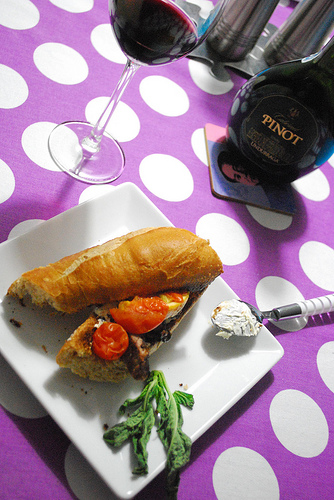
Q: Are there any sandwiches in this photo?
A: Yes, there is a sandwich.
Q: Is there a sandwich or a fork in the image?
A: Yes, there is a sandwich.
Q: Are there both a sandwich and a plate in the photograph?
A: Yes, there are both a sandwich and a plate.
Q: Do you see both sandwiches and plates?
A: Yes, there are both a sandwich and a plate.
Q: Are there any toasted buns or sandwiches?
A: Yes, there is a toasted sandwich.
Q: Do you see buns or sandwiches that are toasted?
A: Yes, the sandwich is toasted.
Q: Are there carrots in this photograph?
A: No, there are no carrots.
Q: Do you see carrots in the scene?
A: No, there are no carrots.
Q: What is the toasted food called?
A: The food is a sandwich.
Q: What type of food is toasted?
A: The food is a sandwich.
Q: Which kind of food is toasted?
A: The food is a sandwich.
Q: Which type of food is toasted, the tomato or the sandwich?
A: The sandwich is toasted.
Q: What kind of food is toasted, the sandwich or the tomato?
A: The sandwich is toasted.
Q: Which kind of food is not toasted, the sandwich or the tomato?
A: The tomato is not toasted.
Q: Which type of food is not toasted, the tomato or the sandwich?
A: The tomato is not toasted.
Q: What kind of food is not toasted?
A: The food is a tomato.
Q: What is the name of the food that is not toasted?
A: The food is a tomato.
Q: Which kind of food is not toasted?
A: The food is a tomato.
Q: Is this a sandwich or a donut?
A: This is a sandwich.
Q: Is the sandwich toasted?
A: Yes, the sandwich is toasted.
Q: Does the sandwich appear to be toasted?
A: Yes, the sandwich is toasted.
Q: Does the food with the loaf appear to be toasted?
A: Yes, the sandwich is toasted.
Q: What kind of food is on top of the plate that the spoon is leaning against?
A: The food is a sandwich.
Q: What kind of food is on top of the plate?
A: The food is a sandwich.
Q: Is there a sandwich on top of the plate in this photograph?
A: Yes, there is a sandwich on top of the plate.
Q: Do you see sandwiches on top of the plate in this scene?
A: Yes, there is a sandwich on top of the plate.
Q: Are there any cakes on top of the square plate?
A: No, there is a sandwich on top of the plate.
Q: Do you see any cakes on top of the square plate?
A: No, there is a sandwich on top of the plate.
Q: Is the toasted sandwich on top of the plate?
A: Yes, the sandwich is on top of the plate.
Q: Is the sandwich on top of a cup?
A: No, the sandwich is on top of the plate.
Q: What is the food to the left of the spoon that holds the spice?
A: The food is a sandwich.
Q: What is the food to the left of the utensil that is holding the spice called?
A: The food is a sandwich.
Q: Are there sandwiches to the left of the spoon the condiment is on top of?
A: Yes, there is a sandwich to the left of the spoon.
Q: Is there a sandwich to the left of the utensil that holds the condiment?
A: Yes, there is a sandwich to the left of the spoon.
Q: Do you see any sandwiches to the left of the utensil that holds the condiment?
A: Yes, there is a sandwich to the left of the spoon.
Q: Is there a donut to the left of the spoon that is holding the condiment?
A: No, there is a sandwich to the left of the spoon.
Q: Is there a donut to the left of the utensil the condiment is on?
A: No, there is a sandwich to the left of the spoon.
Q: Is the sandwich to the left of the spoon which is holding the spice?
A: Yes, the sandwich is to the left of the spoon.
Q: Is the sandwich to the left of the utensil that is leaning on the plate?
A: Yes, the sandwich is to the left of the spoon.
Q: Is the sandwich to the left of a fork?
A: No, the sandwich is to the left of the spoon.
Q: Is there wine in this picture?
A: Yes, there is wine.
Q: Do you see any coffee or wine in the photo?
A: Yes, there is wine.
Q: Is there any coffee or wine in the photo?
A: Yes, there is wine.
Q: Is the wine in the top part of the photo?
A: Yes, the wine is in the top of the image.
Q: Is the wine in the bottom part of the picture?
A: No, the wine is in the top of the image.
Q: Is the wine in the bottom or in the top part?
A: The wine is in the top of the image.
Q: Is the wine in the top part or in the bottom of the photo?
A: The wine is in the top of the image.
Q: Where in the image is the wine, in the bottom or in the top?
A: The wine is in the top of the image.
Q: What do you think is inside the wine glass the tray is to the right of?
A: The wine is inside the wineglass.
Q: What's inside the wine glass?
A: The wine is inside the wineglass.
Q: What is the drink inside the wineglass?
A: The drink is wine.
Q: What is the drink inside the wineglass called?
A: The drink is wine.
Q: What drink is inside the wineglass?
A: The drink is wine.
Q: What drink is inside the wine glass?
A: The drink is wine.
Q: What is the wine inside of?
A: The wine is inside the wineglass.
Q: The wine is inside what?
A: The wine is inside the wineglass.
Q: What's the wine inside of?
A: The wine is inside the wineglass.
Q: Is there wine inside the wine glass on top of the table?
A: Yes, there is wine inside the wine glass.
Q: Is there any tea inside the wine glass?
A: No, there is wine inside the wine glass.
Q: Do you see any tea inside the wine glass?
A: No, there is wine inside the wine glass.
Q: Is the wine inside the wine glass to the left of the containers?
A: Yes, the wine is inside the wineglass.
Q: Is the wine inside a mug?
A: No, the wine is inside the wineglass.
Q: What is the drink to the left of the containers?
A: The drink is wine.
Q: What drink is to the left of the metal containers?
A: The drink is wine.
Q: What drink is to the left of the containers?
A: The drink is wine.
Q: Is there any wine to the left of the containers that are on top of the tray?
A: Yes, there is wine to the left of the containers.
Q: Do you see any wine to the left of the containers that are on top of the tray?
A: Yes, there is wine to the left of the containers.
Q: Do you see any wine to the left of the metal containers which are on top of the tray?
A: Yes, there is wine to the left of the containers.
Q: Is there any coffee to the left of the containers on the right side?
A: No, there is wine to the left of the containers.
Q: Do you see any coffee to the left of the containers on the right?
A: No, there is wine to the left of the containers.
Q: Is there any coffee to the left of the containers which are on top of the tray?
A: No, there is wine to the left of the containers.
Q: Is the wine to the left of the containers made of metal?
A: Yes, the wine is to the left of the containers.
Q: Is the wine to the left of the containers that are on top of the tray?
A: Yes, the wine is to the left of the containers.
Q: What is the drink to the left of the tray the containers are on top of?
A: The drink is wine.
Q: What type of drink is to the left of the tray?
A: The drink is wine.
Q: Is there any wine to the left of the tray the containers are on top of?
A: Yes, there is wine to the left of the tray.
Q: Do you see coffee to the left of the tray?
A: No, there is wine to the left of the tray.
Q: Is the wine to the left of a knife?
A: No, the wine is to the left of a tray.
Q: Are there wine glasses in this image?
A: Yes, there is a wine glass.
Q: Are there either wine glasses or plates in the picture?
A: Yes, there is a wine glass.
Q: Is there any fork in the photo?
A: No, there are no forks.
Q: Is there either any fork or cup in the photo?
A: No, there are no forks or cups.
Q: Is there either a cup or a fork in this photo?
A: No, there are no forks or cups.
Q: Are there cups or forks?
A: No, there are no forks or cups.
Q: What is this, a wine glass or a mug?
A: This is a wine glass.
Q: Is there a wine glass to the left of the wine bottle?
A: Yes, there is a wine glass to the left of the wine bottle.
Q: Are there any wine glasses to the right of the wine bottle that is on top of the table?
A: No, the wine glass is to the left of the wine bottle.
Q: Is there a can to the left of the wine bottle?
A: No, there is a wine glass to the left of the wine bottle.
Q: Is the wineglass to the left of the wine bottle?
A: Yes, the wineglass is to the left of the wine bottle.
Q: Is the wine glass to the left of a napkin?
A: No, the wine glass is to the left of the wine bottle.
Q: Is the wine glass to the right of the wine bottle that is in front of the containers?
A: No, the wine glass is to the left of the wine bottle.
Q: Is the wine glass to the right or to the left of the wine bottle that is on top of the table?
A: The wine glass is to the left of the wine bottle.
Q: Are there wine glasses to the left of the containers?
A: Yes, there is a wine glass to the left of the containers.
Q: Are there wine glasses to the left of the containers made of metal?
A: Yes, there is a wine glass to the left of the containers.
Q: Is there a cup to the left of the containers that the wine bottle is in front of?
A: No, there is a wine glass to the left of the containers.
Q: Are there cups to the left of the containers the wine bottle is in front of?
A: No, there is a wine glass to the left of the containers.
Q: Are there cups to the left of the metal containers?
A: No, there is a wine glass to the left of the containers.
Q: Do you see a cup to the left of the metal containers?
A: No, there is a wine glass to the left of the containers.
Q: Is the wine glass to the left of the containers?
A: Yes, the wine glass is to the left of the containers.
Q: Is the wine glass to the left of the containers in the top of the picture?
A: Yes, the wine glass is to the left of the containers.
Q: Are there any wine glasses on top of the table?
A: Yes, there is a wine glass on top of the table.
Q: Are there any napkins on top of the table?
A: No, there is a wine glass on top of the table.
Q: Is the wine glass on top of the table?
A: Yes, the wine glass is on top of the table.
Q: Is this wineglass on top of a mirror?
A: No, the wineglass is on top of the table.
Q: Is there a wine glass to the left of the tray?
A: Yes, there is a wine glass to the left of the tray.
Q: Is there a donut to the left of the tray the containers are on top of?
A: No, there is a wine glass to the left of the tray.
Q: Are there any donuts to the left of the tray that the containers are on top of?
A: No, there is a wine glass to the left of the tray.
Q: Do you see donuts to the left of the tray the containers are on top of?
A: No, there is a wine glass to the left of the tray.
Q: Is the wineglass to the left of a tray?
A: Yes, the wineglass is to the left of a tray.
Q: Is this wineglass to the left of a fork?
A: No, the wineglass is to the left of a tray.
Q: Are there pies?
A: No, there are no pies.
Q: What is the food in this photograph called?
A: The food is a loaf.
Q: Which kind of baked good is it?
A: The food is a loaf.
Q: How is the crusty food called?
A: The food is a loaf.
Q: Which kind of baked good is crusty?
A: The baked good is a loaf.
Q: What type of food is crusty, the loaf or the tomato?
A: The loaf is crusty.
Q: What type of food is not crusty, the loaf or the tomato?
A: The tomato is not crusty.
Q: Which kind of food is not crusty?
A: The food is a tomato.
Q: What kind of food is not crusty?
A: The food is a tomato.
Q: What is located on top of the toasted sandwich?
A: The loaf is on top of the sandwich.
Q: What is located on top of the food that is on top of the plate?
A: The loaf is on top of the sandwich.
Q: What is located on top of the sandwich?
A: The loaf is on top of the sandwich.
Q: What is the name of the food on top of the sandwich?
A: The food is a loaf.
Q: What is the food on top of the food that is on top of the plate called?
A: The food is a loaf.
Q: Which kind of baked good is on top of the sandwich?
A: The food is a loaf.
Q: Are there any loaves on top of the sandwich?
A: Yes, there is a loaf on top of the sandwich.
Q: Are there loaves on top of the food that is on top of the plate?
A: Yes, there is a loaf on top of the sandwich.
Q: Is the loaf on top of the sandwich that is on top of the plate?
A: Yes, the loaf is on top of the sandwich.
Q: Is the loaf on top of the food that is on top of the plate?
A: Yes, the loaf is on top of the sandwich.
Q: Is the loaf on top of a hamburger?
A: No, the loaf is on top of the sandwich.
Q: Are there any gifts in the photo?
A: No, there are no gifts.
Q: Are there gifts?
A: No, there are no gifts.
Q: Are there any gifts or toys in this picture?
A: No, there are no gifts or toys.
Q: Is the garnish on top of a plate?
A: Yes, the garnish is on top of a plate.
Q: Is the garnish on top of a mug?
A: No, the garnish is on top of a plate.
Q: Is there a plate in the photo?
A: Yes, there is a plate.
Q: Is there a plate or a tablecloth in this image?
A: Yes, there is a plate.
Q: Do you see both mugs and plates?
A: No, there is a plate but no mugs.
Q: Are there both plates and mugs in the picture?
A: No, there is a plate but no mugs.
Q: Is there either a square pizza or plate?
A: Yes, there is a square plate.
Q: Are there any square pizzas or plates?
A: Yes, there is a square plate.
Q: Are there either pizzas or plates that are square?
A: Yes, the plate is square.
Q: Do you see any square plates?
A: Yes, there is a square plate.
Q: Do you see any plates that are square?
A: Yes, there is a square plate.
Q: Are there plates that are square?
A: Yes, there is a plate that is square.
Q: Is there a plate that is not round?
A: Yes, there is a square plate.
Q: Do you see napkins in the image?
A: No, there are no napkins.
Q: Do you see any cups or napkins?
A: No, there are no napkins or cups.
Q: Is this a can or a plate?
A: This is a plate.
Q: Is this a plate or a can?
A: This is a plate.